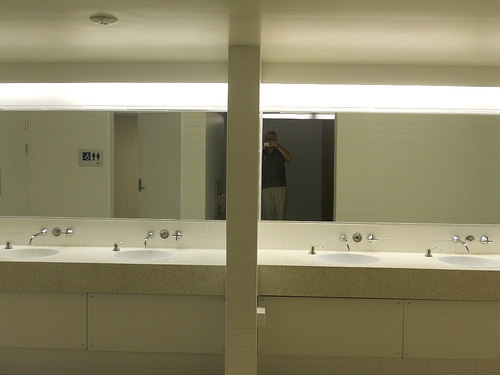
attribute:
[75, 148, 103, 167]
sign — male,  female 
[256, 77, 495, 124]
lights — white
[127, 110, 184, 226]
door — open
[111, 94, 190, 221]
door — open, white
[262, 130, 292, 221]
person — reflection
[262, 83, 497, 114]
light — white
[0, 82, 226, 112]
light — white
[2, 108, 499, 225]
mirror — large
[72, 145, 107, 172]
sign — white, black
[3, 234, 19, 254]
soap dispenser — metallic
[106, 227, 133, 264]
soap dispenser — metallic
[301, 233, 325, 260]
soap dispenser — metallic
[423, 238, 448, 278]
soap dispenser — metallic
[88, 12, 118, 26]
sprinkler — water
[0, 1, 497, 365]
restroom — public